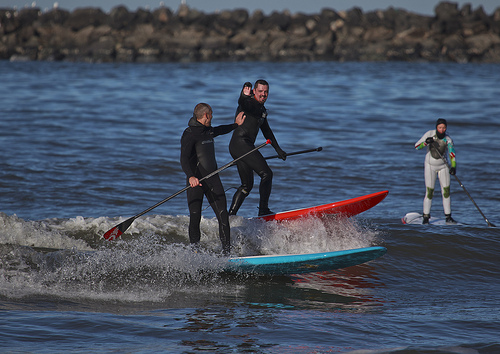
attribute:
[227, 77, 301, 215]
man — standing, close, here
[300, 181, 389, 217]
surfboard — red, long, wet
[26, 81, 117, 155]
water — close, here, calm, blue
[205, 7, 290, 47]
rocks — brown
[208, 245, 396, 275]
board — blue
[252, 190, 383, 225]
paddle board — red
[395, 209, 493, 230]
paddle board — white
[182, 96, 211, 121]
hair — dark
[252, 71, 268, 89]
hair — brown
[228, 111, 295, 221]
wetsuits — black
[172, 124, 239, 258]
wetsuit — black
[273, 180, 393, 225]
surfboard — red